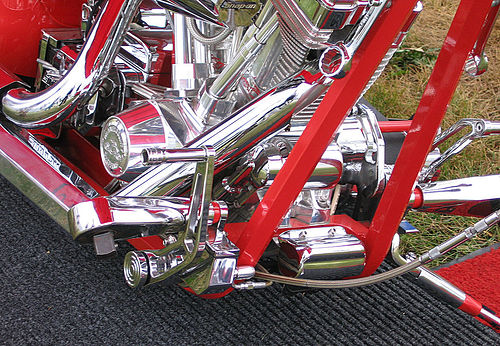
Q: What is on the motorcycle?
A: A chrome engine.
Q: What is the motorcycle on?
A: A ribbed mat.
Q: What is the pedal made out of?
A: Chrome.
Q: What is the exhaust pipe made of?
A: Metallic chrome.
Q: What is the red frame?
A: The body of a motorcycle.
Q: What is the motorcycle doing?
A: Getting repaired.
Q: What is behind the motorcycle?
A: A patch of grass.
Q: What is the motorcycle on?
A: Black rubber.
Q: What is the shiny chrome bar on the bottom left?
A: A metal chrome footrest.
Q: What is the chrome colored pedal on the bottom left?
A: A foot pedal.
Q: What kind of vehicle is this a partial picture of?
A: A red and chrome motorcycle.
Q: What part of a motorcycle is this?
A: A low view of a motorcycle engine.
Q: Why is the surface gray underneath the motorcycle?
A: A rug is under the motorcycle.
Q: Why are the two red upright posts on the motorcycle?
A: They are the suspension struts for the motorcycle.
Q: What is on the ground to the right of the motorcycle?
A: Grass.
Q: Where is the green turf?
A: Near the motorcycle.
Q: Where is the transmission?
A: On the motorcycle.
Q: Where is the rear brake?
A: On right side of motorcycle.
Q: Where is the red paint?
A: On the motorcycle.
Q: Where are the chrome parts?
A: On the engine.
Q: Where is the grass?
A: Behind the motorcycle.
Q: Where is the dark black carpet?
A: Under the motorcycle.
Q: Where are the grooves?
A: In the carpet.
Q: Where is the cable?
A: Bottom of motorcycle.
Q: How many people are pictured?
A: 0.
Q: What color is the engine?
A: Chrome.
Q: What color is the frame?
A: Red.